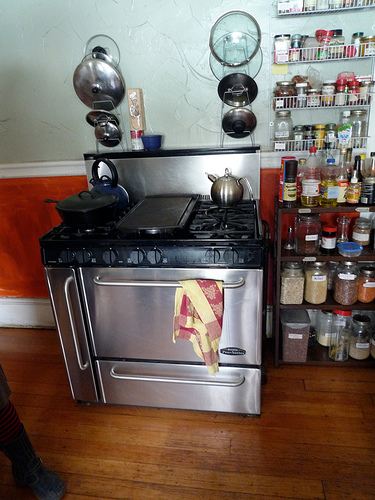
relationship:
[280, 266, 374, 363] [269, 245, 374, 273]
jars in shelf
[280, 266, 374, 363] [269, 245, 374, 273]
jars on shelf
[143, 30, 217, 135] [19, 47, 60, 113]
cracks on wall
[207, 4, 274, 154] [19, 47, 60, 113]
lids on wall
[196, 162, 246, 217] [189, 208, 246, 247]
kettle on stove